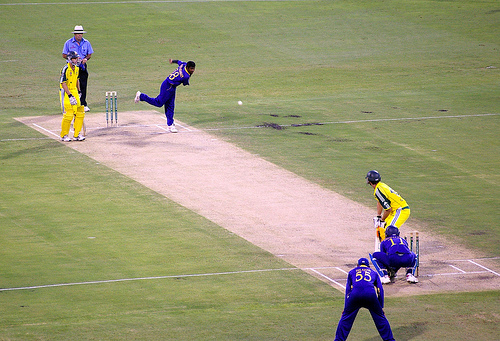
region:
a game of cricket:
[25, 11, 480, 324]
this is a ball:
[225, 89, 250, 109]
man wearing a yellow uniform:
[56, 57, 96, 139]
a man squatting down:
[363, 219, 426, 282]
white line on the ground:
[31, 243, 321, 305]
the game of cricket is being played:
[7, 1, 495, 338]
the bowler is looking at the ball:
[131, 54, 242, 134]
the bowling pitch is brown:
[20, 104, 498, 294]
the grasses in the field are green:
[3, 56, 495, 331]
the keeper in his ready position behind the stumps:
[368, 226, 420, 285]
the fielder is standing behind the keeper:
[334, 226, 417, 336]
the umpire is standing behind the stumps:
[63, 25, 119, 129]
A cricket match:
[16, 3, 483, 332]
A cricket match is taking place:
[8, 5, 489, 330]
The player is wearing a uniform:
[135, 51, 208, 139]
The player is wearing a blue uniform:
[135, 48, 206, 140]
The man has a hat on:
[66, 18, 92, 48]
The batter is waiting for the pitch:
[349, 160, 426, 227]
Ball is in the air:
[236, 95, 245, 109]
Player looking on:
[328, 253, 396, 335]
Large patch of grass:
[31, 184, 140, 259]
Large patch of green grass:
[6, 166, 100, 266]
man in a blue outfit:
[134, 57, 196, 132]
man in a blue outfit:
[332, 258, 394, 340]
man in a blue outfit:
[367, 224, 417, 283]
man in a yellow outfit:
[58, 51, 86, 141]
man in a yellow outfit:
[366, 168, 409, 249]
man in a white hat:
[63, 24, 92, 111]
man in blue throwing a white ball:
[134, 57, 241, 132]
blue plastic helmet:
[365, 168, 381, 180]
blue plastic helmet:
[384, 225, 399, 237]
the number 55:
[354, 269, 372, 283]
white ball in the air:
[233, 95, 245, 109]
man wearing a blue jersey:
[336, 263, 391, 295]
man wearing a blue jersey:
[378, 233, 422, 255]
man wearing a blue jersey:
[166, 59, 186, 87]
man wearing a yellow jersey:
[368, 179, 410, 209]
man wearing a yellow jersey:
[57, 65, 80, 91]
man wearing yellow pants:
[375, 203, 410, 238]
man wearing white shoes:
[130, 88, 143, 112]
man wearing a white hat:
[71, 23, 86, 37]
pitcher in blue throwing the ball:
[133, 43, 203, 138]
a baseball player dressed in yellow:
[46, 48, 101, 140]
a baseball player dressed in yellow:
[347, 163, 422, 239]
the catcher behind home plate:
[367, 218, 424, 278]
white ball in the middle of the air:
[226, 88, 256, 114]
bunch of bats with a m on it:
[101, 74, 130, 136]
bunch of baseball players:
[57, 22, 472, 321]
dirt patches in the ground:
[255, 81, 334, 155]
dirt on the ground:
[202, 156, 331, 248]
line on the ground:
[163, 244, 258, 305]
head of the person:
[332, 155, 384, 205]